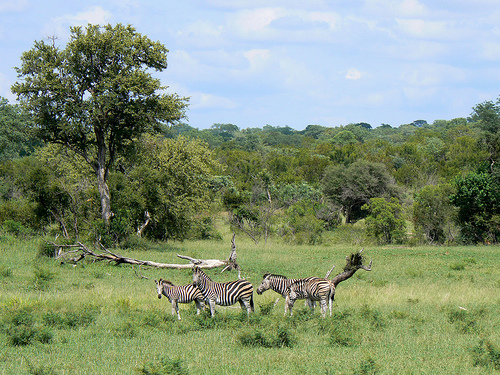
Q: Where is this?
A: This is at the field.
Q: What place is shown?
A: It is a field.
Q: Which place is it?
A: It is a field.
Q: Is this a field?
A: Yes, it is a field.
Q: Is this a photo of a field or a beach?
A: It is showing a field.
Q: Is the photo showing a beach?
A: No, the picture is showing a field.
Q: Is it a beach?
A: No, it is a field.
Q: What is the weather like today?
A: It is cloudy.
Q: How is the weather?
A: It is cloudy.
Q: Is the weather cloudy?
A: Yes, it is cloudy.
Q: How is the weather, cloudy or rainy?
A: It is cloudy.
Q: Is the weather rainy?
A: No, it is cloudy.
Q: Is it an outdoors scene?
A: Yes, it is outdoors.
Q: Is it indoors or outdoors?
A: It is outdoors.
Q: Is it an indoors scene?
A: No, it is outdoors.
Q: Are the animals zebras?
A: Yes, all the animals are zebras.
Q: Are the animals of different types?
A: No, all the animals are zebras.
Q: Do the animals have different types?
A: No, all the animals are zebras.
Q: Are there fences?
A: No, there are no fences.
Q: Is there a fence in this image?
A: No, there are no fences.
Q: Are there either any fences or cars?
A: No, there are no fences or cars.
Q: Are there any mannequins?
A: No, there are no mannequins.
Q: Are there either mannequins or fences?
A: No, there are no mannequins or fences.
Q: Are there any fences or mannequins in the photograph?
A: No, there are no mannequins or fences.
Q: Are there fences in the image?
A: No, there are no fences.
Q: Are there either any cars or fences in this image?
A: No, there are no fences or cars.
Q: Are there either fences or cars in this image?
A: No, there are no fences or cars.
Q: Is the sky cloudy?
A: Yes, the sky is cloudy.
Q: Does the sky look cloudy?
A: Yes, the sky is cloudy.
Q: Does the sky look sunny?
A: No, the sky is cloudy.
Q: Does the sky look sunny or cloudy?
A: The sky is cloudy.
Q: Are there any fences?
A: No, there are no fences.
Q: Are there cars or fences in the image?
A: No, there are no fences or cars.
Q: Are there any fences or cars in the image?
A: No, there are no fences or cars.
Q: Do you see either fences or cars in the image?
A: No, there are no fences or cars.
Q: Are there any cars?
A: No, there are no cars.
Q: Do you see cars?
A: No, there are no cars.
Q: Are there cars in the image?
A: No, there are no cars.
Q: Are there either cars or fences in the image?
A: No, there are no cars or fences.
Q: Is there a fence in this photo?
A: No, there are no fences.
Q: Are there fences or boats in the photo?
A: No, there are no fences or boats.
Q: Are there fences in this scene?
A: No, there are no fences.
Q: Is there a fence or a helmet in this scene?
A: No, there are no fences or helmets.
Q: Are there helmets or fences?
A: No, there are no fences or helmets.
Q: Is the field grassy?
A: Yes, the field is grassy.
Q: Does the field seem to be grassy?
A: Yes, the field is grassy.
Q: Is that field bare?
A: No, the field is grassy.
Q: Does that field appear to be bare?
A: No, the field is grassy.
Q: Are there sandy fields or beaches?
A: No, there is a field but it is grassy.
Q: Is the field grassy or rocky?
A: The field is grassy.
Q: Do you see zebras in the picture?
A: Yes, there is a zebra.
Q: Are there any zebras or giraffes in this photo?
A: Yes, there is a zebra.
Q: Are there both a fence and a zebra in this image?
A: No, there is a zebra but no fences.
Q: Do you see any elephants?
A: No, there are no elephants.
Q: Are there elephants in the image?
A: No, there are no elephants.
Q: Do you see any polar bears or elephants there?
A: No, there are no elephants or polar bears.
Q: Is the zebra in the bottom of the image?
A: Yes, the zebra is in the bottom of the image.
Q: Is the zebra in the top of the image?
A: No, the zebra is in the bottom of the image.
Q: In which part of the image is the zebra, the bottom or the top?
A: The zebra is in the bottom of the image.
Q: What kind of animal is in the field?
A: The animal is a zebra.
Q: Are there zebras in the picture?
A: Yes, there is a zebra.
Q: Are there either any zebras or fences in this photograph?
A: Yes, there is a zebra.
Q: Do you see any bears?
A: No, there are no bears.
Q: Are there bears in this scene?
A: No, there are no bears.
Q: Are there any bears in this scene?
A: No, there are no bears.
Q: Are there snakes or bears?
A: No, there are no bears or snakes.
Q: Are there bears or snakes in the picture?
A: No, there are no bears or snakes.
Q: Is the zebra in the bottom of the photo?
A: Yes, the zebra is in the bottom of the image.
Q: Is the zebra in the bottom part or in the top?
A: The zebra is in the bottom of the image.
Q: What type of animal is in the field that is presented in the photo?
A: The animal is a zebra.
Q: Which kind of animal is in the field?
A: The animal is a zebra.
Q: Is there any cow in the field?
A: No, there is a zebra in the field.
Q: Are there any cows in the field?
A: No, there is a zebra in the field.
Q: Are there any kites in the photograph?
A: No, there are no kites.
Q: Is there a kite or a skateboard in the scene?
A: No, there are no kites or skateboards.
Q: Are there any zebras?
A: Yes, there is a zebra.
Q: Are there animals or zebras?
A: Yes, there is a zebra.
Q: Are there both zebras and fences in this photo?
A: No, there is a zebra but no fences.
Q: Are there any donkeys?
A: No, there are no donkeys.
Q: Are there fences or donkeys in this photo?
A: No, there are no donkeys or fences.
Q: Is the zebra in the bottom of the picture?
A: Yes, the zebra is in the bottom of the image.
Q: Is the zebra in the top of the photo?
A: No, the zebra is in the bottom of the image.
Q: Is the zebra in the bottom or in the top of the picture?
A: The zebra is in the bottom of the image.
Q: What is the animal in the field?
A: The animal is a zebra.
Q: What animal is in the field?
A: The animal is a zebra.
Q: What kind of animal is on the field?
A: The animal is a zebra.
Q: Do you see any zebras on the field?
A: Yes, there is a zebra on the field.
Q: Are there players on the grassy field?
A: No, there is a zebra on the field.